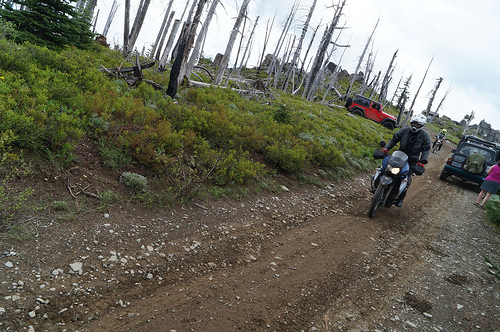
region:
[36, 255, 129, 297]
small rocks on the ground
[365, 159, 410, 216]
a motorcycle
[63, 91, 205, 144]
the green bushes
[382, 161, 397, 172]
headlight on the motorcycle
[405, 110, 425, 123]
a helmet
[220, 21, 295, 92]
tree trunk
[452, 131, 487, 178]
a car on the road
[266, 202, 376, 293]
a brown dirt road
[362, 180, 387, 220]
a front tire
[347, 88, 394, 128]
a red jeep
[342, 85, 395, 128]
red jeep parked off the road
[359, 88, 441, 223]
person riding a motorcycle down the road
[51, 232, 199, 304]
rocks in the dirt road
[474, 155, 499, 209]
person walking down the dirt road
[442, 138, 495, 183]
blue jeep pulled over to the side of the road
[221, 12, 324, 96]
dead trees off the side of the road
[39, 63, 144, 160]
shrubs off the side of the road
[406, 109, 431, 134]
person on motorcycle wearing a white helmet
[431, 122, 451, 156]
person on motorcycle by the red jeep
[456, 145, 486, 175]
spare tire on the back of the jeep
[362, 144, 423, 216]
blue motorcycle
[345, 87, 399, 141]
red jeep with hard cover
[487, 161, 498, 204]
woman in a purple top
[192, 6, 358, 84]
dead trees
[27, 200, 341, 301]
rocks along the road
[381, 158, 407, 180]
motorcycle headlight is on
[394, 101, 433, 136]
cyclist is wearing a white helmet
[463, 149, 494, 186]
spare tire on the back of the car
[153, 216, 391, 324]
dirt path by the rocks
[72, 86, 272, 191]
shrubs by the rocks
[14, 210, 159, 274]
dirt on the road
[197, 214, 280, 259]
dirt on the road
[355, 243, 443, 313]
dirt on the road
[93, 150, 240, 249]
dirt on the road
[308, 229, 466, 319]
dirt on the road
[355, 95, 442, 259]
a man riding the bike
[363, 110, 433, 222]
Person riding motorcycle down dirt path.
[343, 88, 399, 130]
Red jeep parked on grass.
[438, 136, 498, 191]
Blue SUV parked on dirt road.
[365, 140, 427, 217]
Blue motorcycle.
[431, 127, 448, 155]
Person on motorcycle going down dirt road.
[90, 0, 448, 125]
Group of dead trees by dirt road.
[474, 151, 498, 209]
Woman with pink shirt by SUV.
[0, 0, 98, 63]
Evergreen tree by dirt road.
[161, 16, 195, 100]
Dead tree stump by dirt road.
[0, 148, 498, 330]
Dirt road.